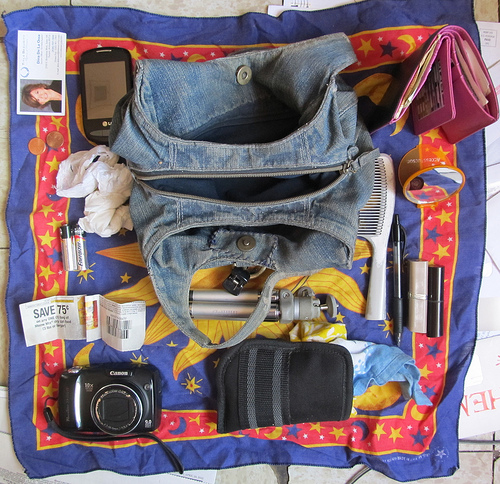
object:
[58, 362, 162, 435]
camera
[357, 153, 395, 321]
comb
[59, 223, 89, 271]
batteries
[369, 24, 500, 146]
wallet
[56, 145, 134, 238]
tissue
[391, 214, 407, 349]
pen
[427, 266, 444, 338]
lipsitck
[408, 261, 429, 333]
lipsitck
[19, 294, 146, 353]
coupon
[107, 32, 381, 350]
purse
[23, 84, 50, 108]
head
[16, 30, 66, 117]
card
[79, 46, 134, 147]
phone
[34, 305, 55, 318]
word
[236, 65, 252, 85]
button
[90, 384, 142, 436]
lens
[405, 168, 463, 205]
mirror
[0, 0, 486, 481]
bandana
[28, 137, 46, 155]
penny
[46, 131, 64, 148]
penny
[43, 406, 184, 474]
strap